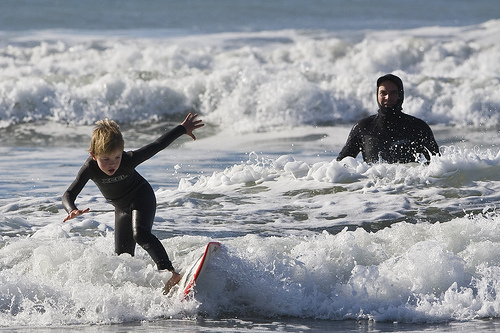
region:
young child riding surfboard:
[52, 89, 276, 330]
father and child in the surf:
[50, 38, 458, 295]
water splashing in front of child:
[47, 71, 242, 321]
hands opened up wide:
[45, 91, 225, 231]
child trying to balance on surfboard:
[20, 95, 230, 305]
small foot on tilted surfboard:
[125, 235, 260, 307]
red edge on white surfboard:
[170, 226, 250, 302]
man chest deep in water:
[315, 55, 450, 197]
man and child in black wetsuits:
[36, 40, 446, 310]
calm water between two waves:
[10, 80, 70, 265]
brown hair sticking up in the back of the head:
[80, 107, 141, 182]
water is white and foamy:
[55, 52, 471, 289]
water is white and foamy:
[110, 88, 333, 310]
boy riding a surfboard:
[40, 107, 246, 320]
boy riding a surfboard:
[83, 124, 212, 276]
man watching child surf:
[318, 64, 442, 197]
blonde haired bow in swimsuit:
[47, 106, 219, 283]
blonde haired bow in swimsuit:
[40, 104, 208, 295]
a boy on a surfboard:
[60, 109, 203, 291]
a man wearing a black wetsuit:
[336, 74, 440, 164]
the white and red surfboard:
[172, 241, 222, 303]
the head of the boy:
[90, 123, 124, 176]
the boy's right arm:
[60, 170, 90, 221]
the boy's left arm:
[133, 112, 203, 163]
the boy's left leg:
[131, 204, 180, 291]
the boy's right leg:
[112, 216, 135, 256]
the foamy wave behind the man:
[2, 39, 499, 122]